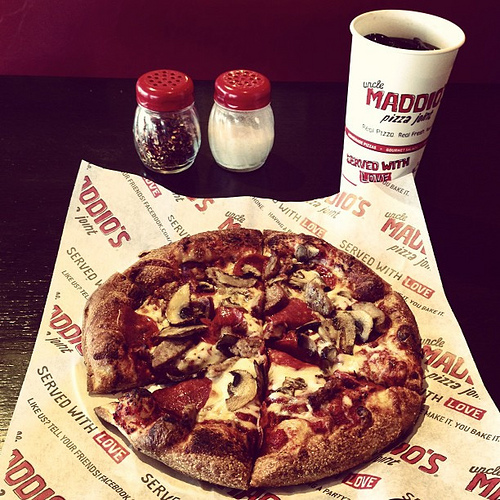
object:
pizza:
[81, 227, 425, 491]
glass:
[133, 100, 276, 174]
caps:
[136, 69, 271, 112]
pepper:
[136, 110, 199, 170]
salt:
[211, 106, 271, 167]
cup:
[339, 9, 466, 193]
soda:
[364, 33, 440, 51]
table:
[1, 78, 500, 499]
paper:
[0, 156, 500, 500]